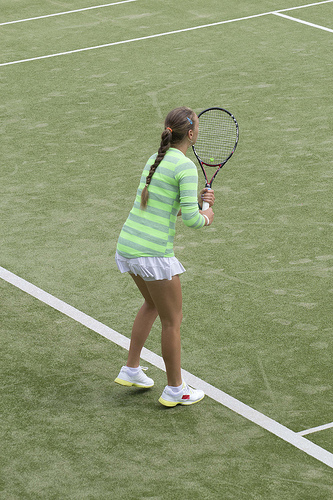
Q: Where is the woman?
A: A tennis court.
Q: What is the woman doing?
A: Playing tennis.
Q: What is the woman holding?
A: A tennis racket.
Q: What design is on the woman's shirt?
A: Stripes.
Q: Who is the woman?
A: A tennis player.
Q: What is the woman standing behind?
A: A white line.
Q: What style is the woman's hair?
A: A braid.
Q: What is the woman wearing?
A: A skirt.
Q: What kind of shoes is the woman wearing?
A: Tennis shoes.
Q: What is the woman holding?
A: A tennis racket.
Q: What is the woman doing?
A: Playing tennis.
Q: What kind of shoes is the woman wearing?
A: Tennis shoes.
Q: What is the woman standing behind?
A: A white line.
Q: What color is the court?
A: Green.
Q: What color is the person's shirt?
A: Green.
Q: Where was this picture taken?
A: On a tennis court.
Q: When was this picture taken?
A: During the day.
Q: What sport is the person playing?
A: Tennis.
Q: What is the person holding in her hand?
A: A tennis racket.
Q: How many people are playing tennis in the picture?
A: One.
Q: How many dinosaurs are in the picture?
A: Zero.